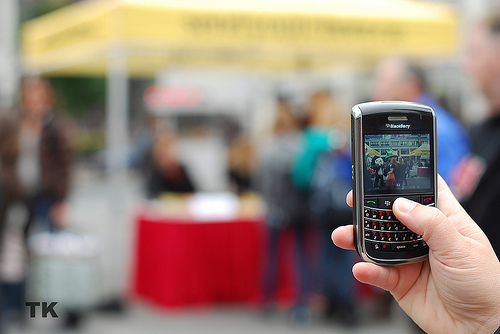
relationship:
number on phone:
[371, 209, 376, 216] [351, 101, 438, 266]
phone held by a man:
[351, 101, 438, 266] [332, 172, 500, 333]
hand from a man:
[331, 172, 500, 333] [332, 172, 500, 333]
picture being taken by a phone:
[1, 0, 500, 332] [351, 101, 438, 266]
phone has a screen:
[351, 101, 438, 266] [365, 133, 430, 191]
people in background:
[2, 14, 497, 327] [0, 0, 499, 333]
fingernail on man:
[397, 198, 416, 213] [332, 172, 500, 333]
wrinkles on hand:
[370, 184, 497, 329] [331, 172, 500, 333]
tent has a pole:
[18, 0, 465, 299] [105, 46, 135, 301]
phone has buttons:
[351, 101, 438, 266] [364, 194, 433, 252]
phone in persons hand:
[351, 101, 438, 266] [331, 172, 500, 333]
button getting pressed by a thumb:
[378, 197, 395, 210] [393, 196, 477, 255]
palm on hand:
[397, 194, 486, 332] [331, 172, 500, 333]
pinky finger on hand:
[351, 261, 399, 292] [331, 172, 500, 333]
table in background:
[136, 210, 376, 308] [0, 0, 499, 333]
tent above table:
[18, 0, 465, 299] [136, 210, 376, 308]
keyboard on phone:
[364, 196, 436, 254] [351, 101, 438, 266]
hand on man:
[331, 172, 500, 333] [332, 172, 500, 333]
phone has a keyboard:
[351, 101, 438, 266] [364, 196, 436, 254]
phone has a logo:
[351, 101, 438, 266] [385, 121, 412, 131]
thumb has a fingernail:
[393, 196, 477, 255] [397, 198, 416, 213]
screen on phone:
[365, 133, 430, 191] [351, 101, 438, 266]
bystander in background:
[1, 74, 73, 325] [0, 0, 499, 333]